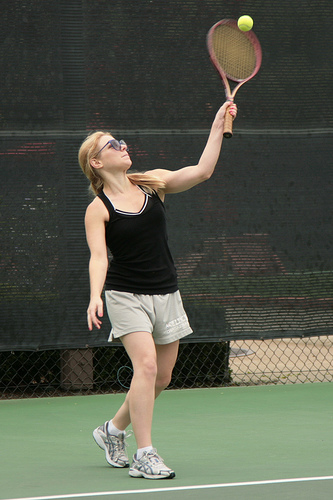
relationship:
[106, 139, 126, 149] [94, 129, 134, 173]
glasses are on face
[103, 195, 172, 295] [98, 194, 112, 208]
shirt has strap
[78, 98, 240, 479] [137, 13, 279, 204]
girl playing living tennis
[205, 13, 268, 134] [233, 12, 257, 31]
racket hitting ball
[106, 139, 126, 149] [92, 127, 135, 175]
glasses on face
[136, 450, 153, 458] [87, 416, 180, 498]
sock on feet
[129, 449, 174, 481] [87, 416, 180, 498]
shoe on feet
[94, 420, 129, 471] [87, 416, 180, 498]
shoe on feet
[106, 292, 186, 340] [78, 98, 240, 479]
shorts on girl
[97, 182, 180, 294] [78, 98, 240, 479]
top on girl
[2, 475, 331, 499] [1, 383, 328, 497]
line on court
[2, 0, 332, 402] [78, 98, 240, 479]
fence behind girl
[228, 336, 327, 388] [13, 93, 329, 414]
pavement behind fence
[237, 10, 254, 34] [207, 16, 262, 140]
ball in front of racket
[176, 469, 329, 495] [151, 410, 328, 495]
line on court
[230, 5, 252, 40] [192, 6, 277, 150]
ball about to contact racket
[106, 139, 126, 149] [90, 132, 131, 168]
glasses on face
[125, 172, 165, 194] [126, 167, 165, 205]
hair laying over shoulder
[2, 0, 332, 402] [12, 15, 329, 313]
fence on edge of court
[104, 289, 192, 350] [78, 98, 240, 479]
shorts on girl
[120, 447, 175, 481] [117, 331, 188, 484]
shoe on foot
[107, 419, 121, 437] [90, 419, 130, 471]
sock on foot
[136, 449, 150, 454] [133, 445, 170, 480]
sock on foot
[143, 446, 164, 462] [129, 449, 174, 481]
shoe lace on shoe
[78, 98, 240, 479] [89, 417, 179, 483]
girl wearing shoes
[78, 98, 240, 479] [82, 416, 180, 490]
girl wearing shoes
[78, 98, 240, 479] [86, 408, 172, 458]
girl wearing socks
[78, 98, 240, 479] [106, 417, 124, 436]
girl wearing sock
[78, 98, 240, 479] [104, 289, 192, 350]
girl wearing shorts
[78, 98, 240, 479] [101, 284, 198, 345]
girl wearing shorts